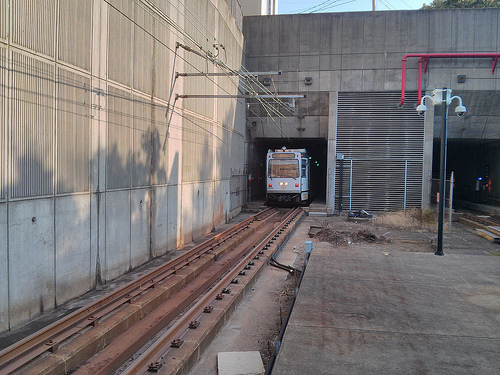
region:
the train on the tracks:
[243, 125, 329, 240]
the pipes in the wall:
[368, 40, 493, 95]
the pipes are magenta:
[372, 45, 495, 84]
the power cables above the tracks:
[134, 11, 315, 108]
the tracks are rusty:
[53, 285, 220, 373]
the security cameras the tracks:
[405, 77, 483, 272]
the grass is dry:
[390, 205, 421, 225]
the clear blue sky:
[280, 0, 295, 5]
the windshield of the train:
[270, 155, 305, 175]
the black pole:
[436, 125, 453, 302]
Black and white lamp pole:
[410, 83, 470, 255]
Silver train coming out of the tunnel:
[259, 146, 313, 205]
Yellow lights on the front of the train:
[280, 178, 287, 188]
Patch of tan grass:
[366, 207, 461, 232]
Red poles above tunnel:
[389, 47, 499, 107]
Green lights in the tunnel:
[300, 148, 330, 171]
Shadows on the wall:
[12, 135, 237, 300]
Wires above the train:
[117, 4, 314, 128]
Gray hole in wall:
[298, 73, 318, 89]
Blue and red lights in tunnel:
[473, 175, 494, 191]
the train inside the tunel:
[243, 128, 330, 225]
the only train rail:
[18, 227, 299, 372]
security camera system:
[407, 81, 475, 220]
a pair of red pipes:
[388, 35, 498, 97]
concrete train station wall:
[6, 47, 253, 283]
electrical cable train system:
[143, 12, 310, 134]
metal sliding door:
[334, 91, 424, 213]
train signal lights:
[263, 176, 307, 194]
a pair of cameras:
[413, 91, 488, 131]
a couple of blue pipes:
[338, 151, 414, 221]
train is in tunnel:
[260, 142, 306, 202]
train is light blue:
[249, 142, 322, 202]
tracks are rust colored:
[44, 181, 292, 361]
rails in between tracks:
[56, 236, 259, 366]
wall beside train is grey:
[28, 22, 248, 220]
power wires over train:
[138, 15, 334, 136]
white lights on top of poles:
[430, 81, 460, 118]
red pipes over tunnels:
[398, 45, 488, 97]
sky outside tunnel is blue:
[280, 3, 333, 13]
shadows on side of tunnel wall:
[23, 152, 219, 275]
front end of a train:
[265, 146, 308, 208]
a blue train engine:
[262, 146, 310, 206]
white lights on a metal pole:
[417, 86, 467, 258]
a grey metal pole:
[439, 89, 447, 255]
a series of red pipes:
[399, 51, 498, 108]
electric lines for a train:
[3, 0, 318, 136]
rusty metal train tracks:
[0, 203, 310, 371]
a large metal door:
[335, 90, 425, 212]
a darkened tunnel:
[433, 132, 498, 215]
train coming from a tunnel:
[248, 137, 328, 204]